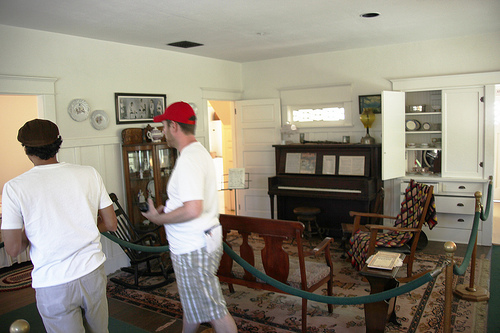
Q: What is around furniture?
A: Green velvet rope.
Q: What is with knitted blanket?
A: Wood rocking chair.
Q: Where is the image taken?
A: Living room.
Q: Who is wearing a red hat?
A: Person on the right.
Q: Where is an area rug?
A: On the floor.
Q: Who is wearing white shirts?
A: Both people.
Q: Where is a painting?
A: On the wall.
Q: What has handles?
A: The drawers.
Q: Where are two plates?
A: On the wall.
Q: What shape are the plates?
A: Round.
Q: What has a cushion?
A: A wooden couch.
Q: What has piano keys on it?
A: A piano.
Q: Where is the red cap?
A: On a plump man with striped shorts.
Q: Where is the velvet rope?
A: To the right of the two standing people.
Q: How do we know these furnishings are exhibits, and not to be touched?
A: The velvet rope is meant to keep people from touching them.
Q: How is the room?
A: Neat.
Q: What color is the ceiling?
A: White.